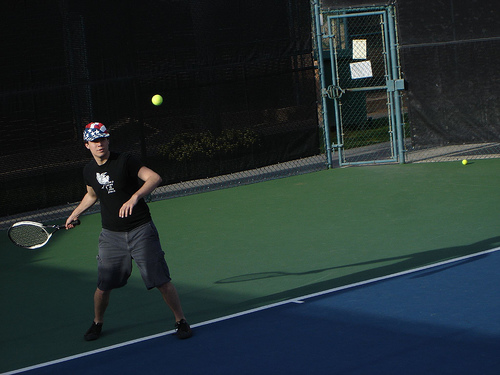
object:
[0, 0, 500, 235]
building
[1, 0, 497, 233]
fence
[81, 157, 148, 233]
tee shirt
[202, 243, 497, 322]
line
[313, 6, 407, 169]
door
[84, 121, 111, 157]
head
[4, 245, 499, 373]
inbounds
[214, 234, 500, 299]
shadow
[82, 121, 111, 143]
cap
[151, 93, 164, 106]
tennis ball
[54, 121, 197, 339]
man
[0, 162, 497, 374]
tennis court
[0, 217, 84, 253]
racket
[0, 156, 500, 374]
ground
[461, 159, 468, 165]
tennis ball